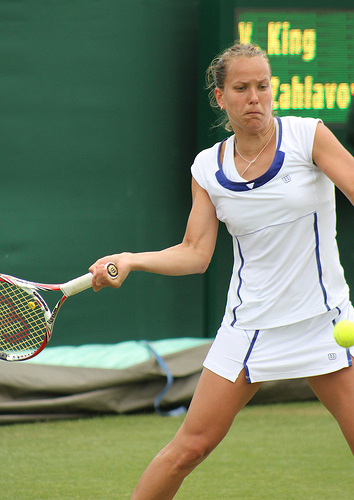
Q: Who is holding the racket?
A: A female tennis player.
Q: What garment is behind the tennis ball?
A: A tennis skirt.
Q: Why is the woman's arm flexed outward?
A: To hit the ball.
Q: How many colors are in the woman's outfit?
A: Two.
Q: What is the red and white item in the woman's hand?
A: A tennis racket.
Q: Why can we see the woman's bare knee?
A: She is wearing a skirt.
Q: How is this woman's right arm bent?
A: At elbow.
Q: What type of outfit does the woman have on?
A: Tennis.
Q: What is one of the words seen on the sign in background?
A: King.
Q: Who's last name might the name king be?
A: Woman with tennis racket.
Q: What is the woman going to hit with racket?
A: Tennis ball.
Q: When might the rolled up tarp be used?
A: When ground is wet.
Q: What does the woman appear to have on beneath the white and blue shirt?
A: Tank top.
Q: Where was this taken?
A: Tennis court.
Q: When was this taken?
A: During a tennis match.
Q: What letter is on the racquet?
A: W.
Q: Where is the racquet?
A: In the woman's right hand.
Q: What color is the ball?
A: Yellow.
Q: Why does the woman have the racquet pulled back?
A: Going to hit the ball.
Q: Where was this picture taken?
A: At a tennis match.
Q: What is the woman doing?
A: Playing tennis.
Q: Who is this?
A: A tennis player.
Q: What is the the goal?
A: To hit the ball.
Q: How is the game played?
A: By hitting the ball with the racquet.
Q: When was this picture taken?
A: Yesterday.